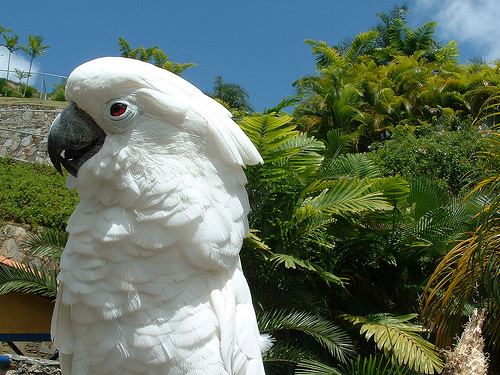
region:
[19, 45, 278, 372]
white parrot looking sideways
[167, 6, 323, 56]
blue skies in the distance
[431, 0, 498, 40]
white clouds in the blue sky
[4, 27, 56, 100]
palm trees in the distance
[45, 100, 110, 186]
black beak of a parrot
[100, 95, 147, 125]
red left eye of a parrot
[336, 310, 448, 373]
tropical foliage in the bushes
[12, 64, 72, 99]
silver fence in the background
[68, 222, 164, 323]
white feathers of a parrot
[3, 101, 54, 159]
stone wall in the back of parrot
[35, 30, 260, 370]
White bird with black beak and red eye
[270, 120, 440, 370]
Large bright green palm leaves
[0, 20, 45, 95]
Tall, bright green palm trees in the background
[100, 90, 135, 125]
Red bird eye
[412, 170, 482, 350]
Yellow palm leaves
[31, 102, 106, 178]
Curved black bird beak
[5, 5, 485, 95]
Blue sky in the background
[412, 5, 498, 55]
Puffy white cloud in back corner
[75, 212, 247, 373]
Ruffled white bird feathers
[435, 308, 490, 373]
Tan straw next to trees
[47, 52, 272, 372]
the feathers on the bird are white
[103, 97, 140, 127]
the eye of the bird is black and red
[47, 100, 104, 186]
the bird's beak is black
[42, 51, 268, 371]
the bird is an umbrella cockatoo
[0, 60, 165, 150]
a rail and fence is behind the bird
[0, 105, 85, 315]
rock walls are on the hillside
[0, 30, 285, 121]
palms are on top of the hill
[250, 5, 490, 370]
different species of palms are near the bird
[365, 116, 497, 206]
a flowering bush is among the palms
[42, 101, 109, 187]
the bird's beak is slightly open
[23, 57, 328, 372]
bird has white feathers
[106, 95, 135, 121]
red eye on white bird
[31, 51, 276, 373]
white cockatoo with black beak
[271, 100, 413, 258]
green palm fronds behind bird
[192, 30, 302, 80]
clear dark blue sky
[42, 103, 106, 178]
sharp black pointy beak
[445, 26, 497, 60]
small white puffy cloud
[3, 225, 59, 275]
stone wall under bushes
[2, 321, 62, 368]
blue metal ladder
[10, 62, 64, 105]
chain link fence on to of hill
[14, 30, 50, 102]
tall palm tree on top of hill